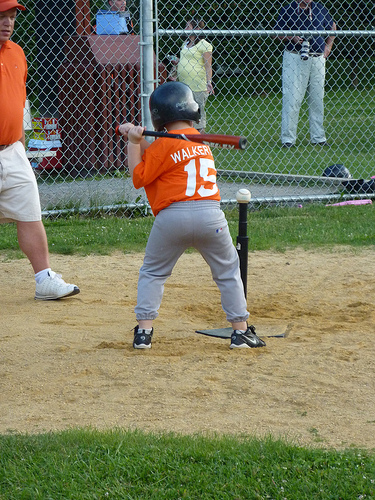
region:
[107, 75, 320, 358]
A boy playing tee ball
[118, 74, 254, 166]
A boy holding a bat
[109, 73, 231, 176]
A boy wearing a black helmet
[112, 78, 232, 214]
A boy wearing an orange shirt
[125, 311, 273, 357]
A boy wearing black and white Nikes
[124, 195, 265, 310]
A boy wearing gray pants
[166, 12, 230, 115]
A pregnant woman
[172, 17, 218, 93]
A woman in a yellow shirt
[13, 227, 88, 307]
A man wearing white shoes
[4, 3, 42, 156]
A man wearing an orange shirt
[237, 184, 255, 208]
A small white baseball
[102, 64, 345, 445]
A boy playing teeball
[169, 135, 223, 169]
The jersey says "Walker"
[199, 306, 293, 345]
Home plate by the batter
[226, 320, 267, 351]
Black shoes on the boy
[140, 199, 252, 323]
The boy wears grey pants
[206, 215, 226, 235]
A pocket in the boy's pants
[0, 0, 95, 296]
The boy's coach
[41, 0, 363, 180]
A chain link fence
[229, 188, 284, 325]
A black baseball stand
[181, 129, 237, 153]
the bat is red black and silver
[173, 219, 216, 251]
the pants are gray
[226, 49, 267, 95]
the gate is silver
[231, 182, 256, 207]
the baseball is sitting on the tee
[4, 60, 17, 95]
the shirt is orange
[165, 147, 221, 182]
the word are white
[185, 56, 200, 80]
the shirt is yellow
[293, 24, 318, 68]
the man is holding a camera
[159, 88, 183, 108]
the helmet is black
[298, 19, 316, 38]
the shirt is blue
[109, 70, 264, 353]
back of child in uniform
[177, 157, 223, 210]
white number on orange shirt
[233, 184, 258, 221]
white ball on black pole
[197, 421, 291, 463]
edge of green grass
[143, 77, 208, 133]
black helmet on head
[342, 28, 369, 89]
metal pole on chain link fence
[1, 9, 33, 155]
man in orange shirt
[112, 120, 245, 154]
two hands on baseball bat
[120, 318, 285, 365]
two feet on dirt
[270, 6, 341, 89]
man behind fence holding camera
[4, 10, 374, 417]
a kid's tee ball game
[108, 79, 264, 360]
child preparing to hit a ball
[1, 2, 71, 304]
a man wearing an orange shirt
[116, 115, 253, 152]
a red and black tee ball bat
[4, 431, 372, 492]
long green grass in the foreground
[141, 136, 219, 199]
orange uniform with the number 15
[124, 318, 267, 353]
kids' black and white athletic shoes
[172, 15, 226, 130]
pregnant woman in a yellow shirt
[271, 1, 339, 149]
man with a camera in a blue shirt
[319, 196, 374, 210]
pink bat lying in the grass